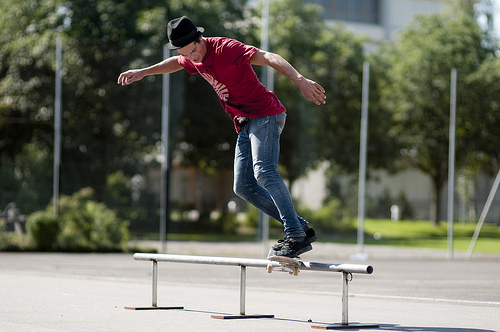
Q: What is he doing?
A: Skating.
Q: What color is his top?
A: Red.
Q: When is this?
A: Daytime.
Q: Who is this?
A: A man.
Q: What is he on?
A: Skateboard.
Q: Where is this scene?
A: In a parking lot.